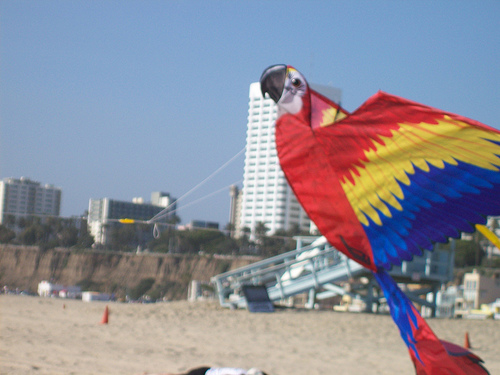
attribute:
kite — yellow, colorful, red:
[260, 63, 500, 374]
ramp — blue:
[211, 240, 373, 312]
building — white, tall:
[241, 80, 340, 245]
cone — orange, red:
[102, 306, 110, 324]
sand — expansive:
[1, 293, 498, 374]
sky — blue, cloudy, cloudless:
[1, 1, 498, 248]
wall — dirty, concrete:
[462, 275, 495, 313]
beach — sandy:
[0, 292, 499, 374]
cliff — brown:
[2, 244, 334, 308]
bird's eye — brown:
[293, 78, 301, 90]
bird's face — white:
[277, 65, 307, 119]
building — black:
[107, 221, 179, 254]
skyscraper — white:
[242, 82, 337, 250]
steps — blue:
[211, 238, 373, 310]